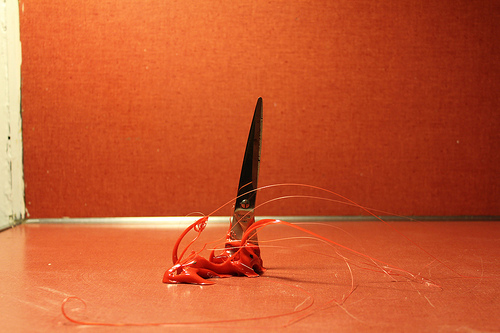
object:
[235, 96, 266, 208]
blades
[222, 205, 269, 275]
handle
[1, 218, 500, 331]
floor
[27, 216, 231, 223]
light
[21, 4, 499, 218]
door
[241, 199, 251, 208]
rivet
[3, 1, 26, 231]
frame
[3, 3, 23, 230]
paint